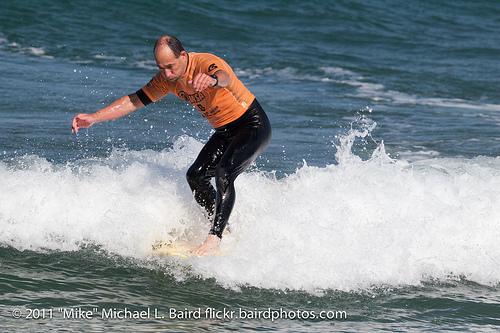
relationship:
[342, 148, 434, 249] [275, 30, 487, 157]
waves on ocean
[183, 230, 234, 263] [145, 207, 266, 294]
feet on surfboard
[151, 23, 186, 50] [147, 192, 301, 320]
hair on surfer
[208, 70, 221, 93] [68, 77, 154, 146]
watch on arm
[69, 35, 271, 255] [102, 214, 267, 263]
man on surfboard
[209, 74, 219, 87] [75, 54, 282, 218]
watch on man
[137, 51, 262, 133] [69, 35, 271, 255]
shirt on man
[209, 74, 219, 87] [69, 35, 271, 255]
watch on man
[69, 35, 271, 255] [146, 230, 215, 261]
man on surfboard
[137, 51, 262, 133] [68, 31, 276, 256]
shirt on man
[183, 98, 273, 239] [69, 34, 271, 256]
pants on surfer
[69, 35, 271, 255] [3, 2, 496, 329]
man in ocean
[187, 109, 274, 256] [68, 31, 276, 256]
wetsuit on man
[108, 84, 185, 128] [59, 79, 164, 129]
shadow on arm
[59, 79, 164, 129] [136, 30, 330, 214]
arm on man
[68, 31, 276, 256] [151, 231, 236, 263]
man on surfboard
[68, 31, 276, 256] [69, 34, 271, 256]
man a surfer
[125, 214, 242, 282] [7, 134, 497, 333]
surfboard on ocean water